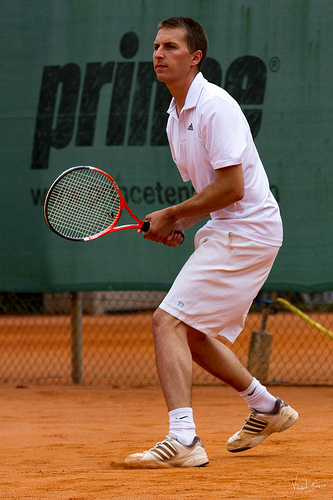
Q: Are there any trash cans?
A: No, there are no trash cans.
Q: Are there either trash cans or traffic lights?
A: No, there are no trash cans or traffic lights.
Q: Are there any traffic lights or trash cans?
A: No, there are no trash cans or traffic lights.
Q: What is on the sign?
A: The letter is on the sign.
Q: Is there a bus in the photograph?
A: No, there are no buses.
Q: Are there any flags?
A: No, there are no flags.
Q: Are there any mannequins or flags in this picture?
A: No, there are no flags or mannequins.